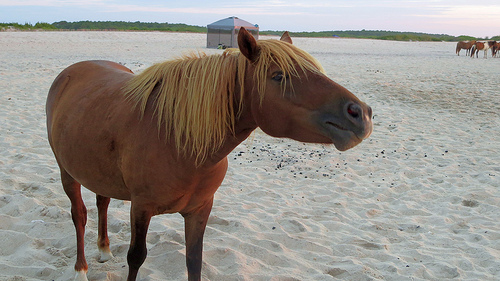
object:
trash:
[232, 151, 458, 187]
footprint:
[204, 247, 232, 271]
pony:
[45, 26, 372, 281]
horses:
[456, 40, 500, 59]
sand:
[353, 161, 499, 281]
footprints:
[252, 151, 495, 276]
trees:
[0, 20, 208, 34]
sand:
[0, 31, 500, 281]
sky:
[0, 0, 499, 40]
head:
[250, 30, 371, 151]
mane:
[119, 38, 326, 168]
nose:
[343, 101, 373, 122]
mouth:
[317, 114, 372, 151]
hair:
[74, 268, 89, 280]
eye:
[271, 71, 289, 81]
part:
[316, 100, 366, 151]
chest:
[132, 121, 228, 213]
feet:
[71, 259, 88, 281]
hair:
[254, 39, 326, 107]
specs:
[257, 148, 322, 181]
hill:
[0, 19, 500, 41]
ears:
[237, 26, 258, 63]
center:
[206, 16, 258, 49]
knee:
[126, 248, 147, 267]